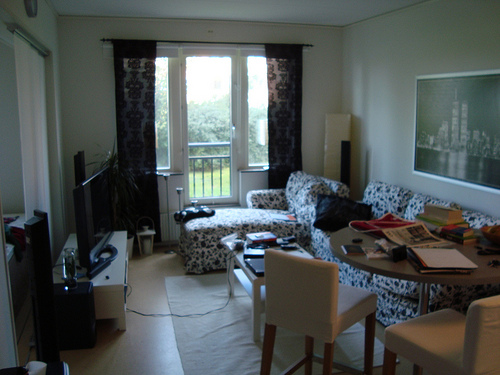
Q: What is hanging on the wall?
A: Picture.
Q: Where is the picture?
A: Hanging on the wall.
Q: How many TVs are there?
A: 1.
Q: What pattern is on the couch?
A: Flowers.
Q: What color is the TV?
A: Black.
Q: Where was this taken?
A: Living room.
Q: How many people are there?
A: 0.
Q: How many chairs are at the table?
A: 2.